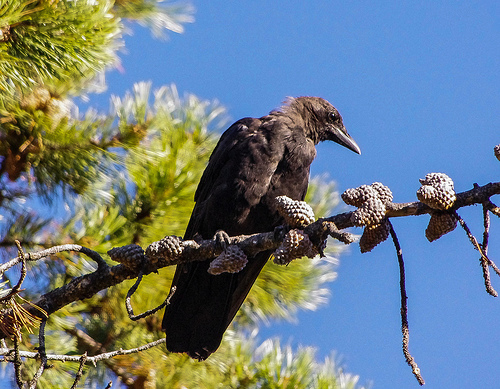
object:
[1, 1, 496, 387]
tree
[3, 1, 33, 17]
leaves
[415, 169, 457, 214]
pine cones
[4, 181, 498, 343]
branch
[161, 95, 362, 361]
bird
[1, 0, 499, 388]
sky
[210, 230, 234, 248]
feet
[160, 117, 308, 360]
wing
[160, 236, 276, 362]
tail feathers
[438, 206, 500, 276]
twigs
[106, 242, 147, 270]
pine cone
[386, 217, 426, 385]
twig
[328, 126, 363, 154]
beak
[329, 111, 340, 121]
eye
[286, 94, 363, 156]
head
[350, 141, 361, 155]
tip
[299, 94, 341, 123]
top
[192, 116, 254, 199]
feathers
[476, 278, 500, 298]
tip